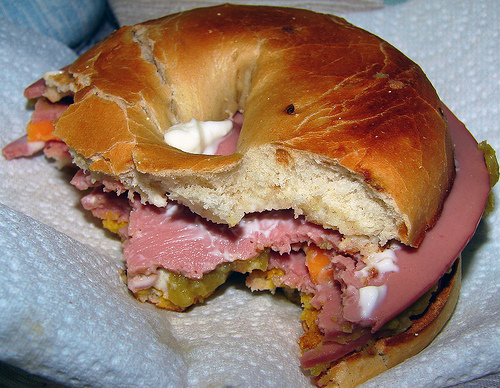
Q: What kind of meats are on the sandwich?
A: Bologna and ham.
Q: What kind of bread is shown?
A: Bagel.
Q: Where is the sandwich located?
A: On a paper towel.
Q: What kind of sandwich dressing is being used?
A: Mayonnaise.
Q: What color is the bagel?
A: Tan and brown.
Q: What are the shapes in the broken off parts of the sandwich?
A: Bite marks.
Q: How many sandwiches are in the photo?
A: One.